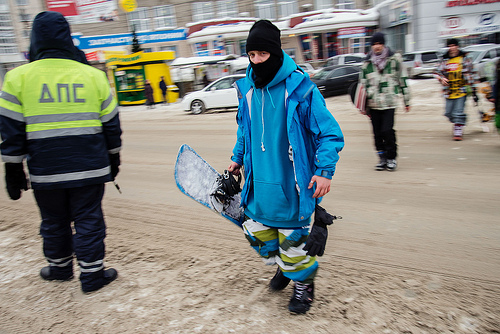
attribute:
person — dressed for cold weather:
[0, 9, 127, 294]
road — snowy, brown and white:
[7, 119, 496, 296]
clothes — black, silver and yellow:
[0, 47, 121, 273]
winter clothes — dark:
[220, 18, 340, 315]